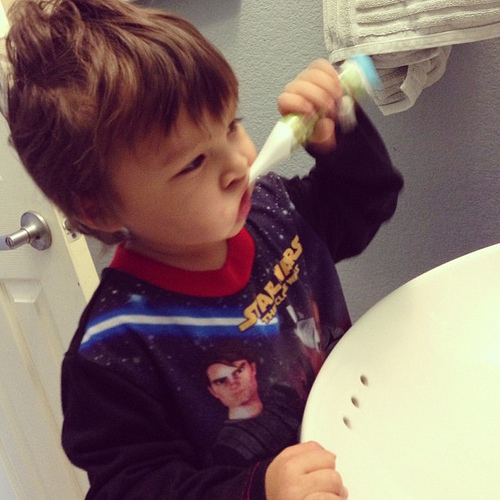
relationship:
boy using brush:
[15, 11, 334, 288] [266, 54, 385, 163]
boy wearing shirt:
[15, 11, 334, 288] [113, 251, 316, 435]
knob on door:
[8, 222, 44, 248] [10, 269, 60, 372]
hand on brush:
[288, 65, 330, 94] [266, 54, 385, 163]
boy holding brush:
[15, 11, 334, 288] [266, 54, 385, 163]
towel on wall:
[328, 5, 464, 63] [263, 10, 305, 50]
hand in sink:
[288, 65, 330, 94] [358, 251, 497, 494]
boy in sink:
[15, 11, 334, 288] [358, 251, 497, 494]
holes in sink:
[336, 368, 370, 410] [358, 251, 497, 494]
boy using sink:
[15, 11, 334, 288] [358, 251, 497, 494]